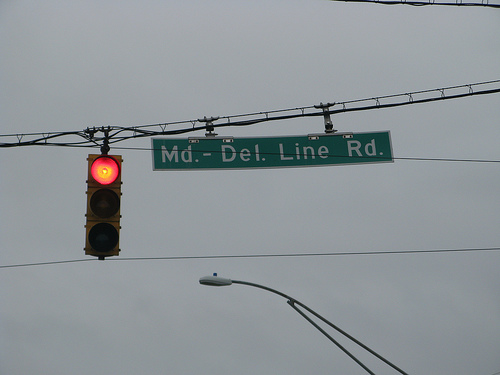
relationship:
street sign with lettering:
[150, 128, 394, 172] [160, 136, 383, 164]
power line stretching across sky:
[0, 246, 499, 269] [1, 0, 499, 375]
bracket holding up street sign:
[306, 102, 355, 141] [150, 128, 394, 172]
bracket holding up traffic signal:
[97, 126, 115, 155] [82, 153, 124, 260]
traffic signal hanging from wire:
[82, 153, 124, 260] [0, 79, 500, 149]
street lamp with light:
[198, 272, 408, 374] [212, 272, 219, 278]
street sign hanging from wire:
[150, 128, 394, 172] [0, 79, 500, 149]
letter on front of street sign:
[160, 143, 179, 163] [150, 128, 394, 172]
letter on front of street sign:
[221, 144, 236, 163] [150, 128, 394, 172]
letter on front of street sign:
[347, 139, 363, 158] [150, 128, 394, 172]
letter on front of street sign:
[302, 145, 317, 160] [150, 128, 394, 172]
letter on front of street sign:
[278, 141, 294, 161] [150, 128, 394, 172]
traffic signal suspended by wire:
[82, 153, 124, 260] [0, 79, 500, 149]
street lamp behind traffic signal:
[198, 272, 408, 374] [82, 153, 124, 260]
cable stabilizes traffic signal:
[0, 79, 500, 149] [82, 153, 124, 260]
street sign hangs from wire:
[150, 128, 394, 172] [0, 79, 500, 149]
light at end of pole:
[212, 272, 219, 278] [232, 279, 408, 375]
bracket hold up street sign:
[187, 116, 236, 144] [150, 128, 394, 172]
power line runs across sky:
[0, 246, 499, 269] [1, 0, 499, 375]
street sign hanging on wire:
[150, 128, 394, 172] [0, 79, 500, 149]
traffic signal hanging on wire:
[82, 153, 124, 260] [0, 79, 500, 149]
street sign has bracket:
[150, 128, 394, 172] [306, 102, 355, 141]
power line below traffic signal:
[0, 246, 499, 269] [82, 153, 124, 260]